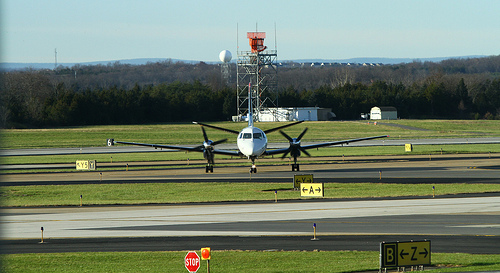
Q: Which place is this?
A: It is an airport.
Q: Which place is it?
A: It is an airport.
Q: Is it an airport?
A: Yes, it is an airport.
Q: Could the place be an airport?
A: Yes, it is an airport.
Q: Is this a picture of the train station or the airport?
A: It is showing the airport.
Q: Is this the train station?
A: No, it is the airport.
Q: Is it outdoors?
A: Yes, it is outdoors.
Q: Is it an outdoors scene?
A: Yes, it is outdoors.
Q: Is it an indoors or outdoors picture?
A: It is outdoors.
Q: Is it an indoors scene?
A: No, it is outdoors.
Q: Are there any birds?
A: No, there are no birds.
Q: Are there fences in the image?
A: No, there are no fences.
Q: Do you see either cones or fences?
A: No, there are no fences or cones.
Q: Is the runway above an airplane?
A: Yes, the runway is above an airplane.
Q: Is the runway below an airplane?
A: No, the runway is above an airplane.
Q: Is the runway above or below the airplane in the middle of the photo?
A: The runway is above the airplane.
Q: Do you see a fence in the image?
A: No, there are no fences.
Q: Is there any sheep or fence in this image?
A: No, there are no fences or sheep.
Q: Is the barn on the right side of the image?
A: Yes, the barn is on the right of the image.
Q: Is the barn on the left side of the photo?
A: No, the barn is on the right of the image.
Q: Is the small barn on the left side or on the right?
A: The barn is on the right of the image.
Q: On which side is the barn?
A: The barn is on the right of the image.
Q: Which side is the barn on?
A: The barn is on the right of the image.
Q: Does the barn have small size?
A: Yes, the barn is small.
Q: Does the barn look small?
A: Yes, the barn is small.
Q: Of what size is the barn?
A: The barn is small.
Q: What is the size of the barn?
A: The barn is small.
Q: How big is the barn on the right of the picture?
A: The barn is small.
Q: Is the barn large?
A: No, the barn is small.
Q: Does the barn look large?
A: No, the barn is small.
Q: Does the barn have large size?
A: No, the barn is small.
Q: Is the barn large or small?
A: The barn is small.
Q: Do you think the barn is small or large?
A: The barn is small.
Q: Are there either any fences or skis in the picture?
A: No, there are no fences or skis.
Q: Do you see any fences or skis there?
A: No, there are no fences or skis.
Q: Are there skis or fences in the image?
A: No, there are no fences or skis.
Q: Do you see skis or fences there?
A: No, there are no fences or skis.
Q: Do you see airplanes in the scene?
A: Yes, there is an airplane.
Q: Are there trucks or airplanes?
A: Yes, there is an airplane.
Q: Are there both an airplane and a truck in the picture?
A: No, there is an airplane but no trucks.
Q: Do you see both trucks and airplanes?
A: No, there is an airplane but no trucks.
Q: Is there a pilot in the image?
A: No, there are no pilots.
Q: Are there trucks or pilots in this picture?
A: No, there are no pilots or trucks.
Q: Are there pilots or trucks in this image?
A: No, there are no pilots or trucks.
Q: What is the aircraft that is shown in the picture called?
A: The aircraft is an airplane.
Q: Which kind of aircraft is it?
A: The aircraft is an airplane.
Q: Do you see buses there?
A: No, there are no buses.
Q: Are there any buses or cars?
A: No, there are no buses or cars.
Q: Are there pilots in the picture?
A: No, there are no pilots.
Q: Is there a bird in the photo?
A: No, there are no birds.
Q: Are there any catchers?
A: No, there are no catchers.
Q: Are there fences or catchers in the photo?
A: No, there are no catchers or fences.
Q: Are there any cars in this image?
A: No, there are no cars.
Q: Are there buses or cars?
A: No, there are no cars or buses.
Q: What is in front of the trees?
A: The buildings are in front of the trees.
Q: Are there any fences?
A: No, there are no fences.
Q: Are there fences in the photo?
A: No, there are no fences.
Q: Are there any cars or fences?
A: No, there are no fences or cars.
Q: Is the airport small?
A: Yes, the airport is small.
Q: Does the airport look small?
A: Yes, the airport is small.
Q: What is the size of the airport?
A: The airport is small.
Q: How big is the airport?
A: The airport is small.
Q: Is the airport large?
A: No, the airport is small.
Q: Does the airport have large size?
A: No, the airport is small.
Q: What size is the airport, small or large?
A: The airport is small.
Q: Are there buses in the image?
A: No, there are no buses.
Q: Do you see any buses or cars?
A: No, there are no buses or cars.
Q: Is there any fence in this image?
A: No, there are no fences.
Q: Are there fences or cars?
A: No, there are no fences or cars.